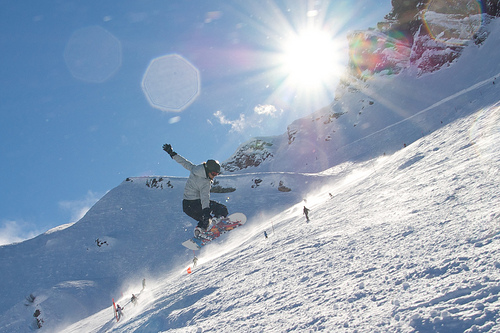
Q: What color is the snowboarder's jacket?
A: White.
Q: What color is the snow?
A: White.